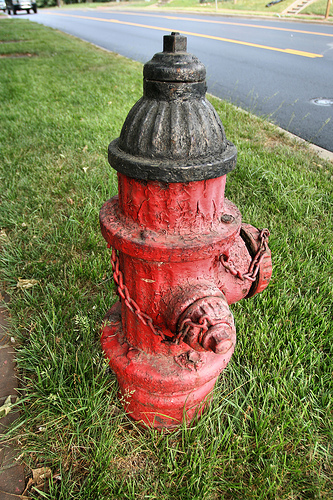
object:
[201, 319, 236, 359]
flange nut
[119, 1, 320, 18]
sidewalk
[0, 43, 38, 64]
hole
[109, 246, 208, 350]
chain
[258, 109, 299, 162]
curb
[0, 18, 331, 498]
grass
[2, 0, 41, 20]
car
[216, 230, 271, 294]
chain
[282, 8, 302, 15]
steps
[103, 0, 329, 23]
hill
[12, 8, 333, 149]
street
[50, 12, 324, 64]
lines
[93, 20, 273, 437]
fire hydrant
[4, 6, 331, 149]
road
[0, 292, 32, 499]
dirt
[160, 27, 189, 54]
nut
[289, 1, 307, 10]
steps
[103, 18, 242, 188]
hydrant top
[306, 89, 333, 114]
utility access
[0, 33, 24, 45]
hole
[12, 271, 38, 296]
leave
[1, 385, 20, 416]
leave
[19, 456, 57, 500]
leave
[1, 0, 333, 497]
ground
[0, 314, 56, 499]
cement